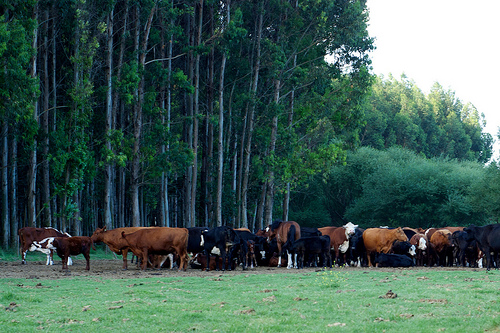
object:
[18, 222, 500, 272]
cow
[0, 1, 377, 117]
tops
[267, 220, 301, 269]
horse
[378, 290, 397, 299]
excrement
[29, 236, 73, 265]
calf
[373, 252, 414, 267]
cow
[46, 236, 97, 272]
calf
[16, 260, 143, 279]
ground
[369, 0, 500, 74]
sunny skies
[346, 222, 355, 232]
face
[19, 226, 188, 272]
brown cow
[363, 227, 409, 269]
browncows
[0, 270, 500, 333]
grass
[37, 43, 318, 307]
trees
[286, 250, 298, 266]
white legs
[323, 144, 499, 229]
fluffy trees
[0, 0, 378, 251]
trees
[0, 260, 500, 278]
dirt patch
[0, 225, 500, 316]
pasture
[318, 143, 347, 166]
leaves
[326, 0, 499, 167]
sun shining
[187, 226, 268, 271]
black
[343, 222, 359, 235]
cow's head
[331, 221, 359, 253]
color white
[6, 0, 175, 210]
left side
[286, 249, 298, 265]
legs